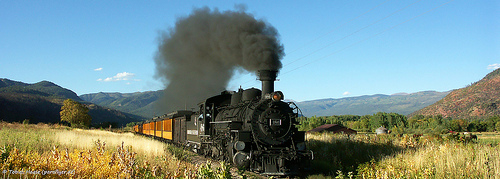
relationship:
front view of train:
[243, 90, 291, 147] [147, 81, 320, 171]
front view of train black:
[229, 90, 306, 176] [211, 107, 232, 129]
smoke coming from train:
[183, 23, 277, 59] [147, 81, 320, 171]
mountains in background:
[27, 76, 111, 100] [17, 40, 100, 87]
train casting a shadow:
[147, 81, 320, 171] [325, 138, 393, 169]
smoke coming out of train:
[183, 23, 277, 59] [147, 81, 320, 171]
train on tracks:
[147, 81, 320, 171] [187, 146, 211, 165]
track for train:
[267, 170, 295, 178] [147, 81, 320, 171]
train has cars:
[147, 81, 320, 171] [144, 117, 187, 138]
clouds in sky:
[93, 56, 139, 83] [311, 29, 375, 65]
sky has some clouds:
[311, 29, 375, 65] [93, 56, 139, 83]